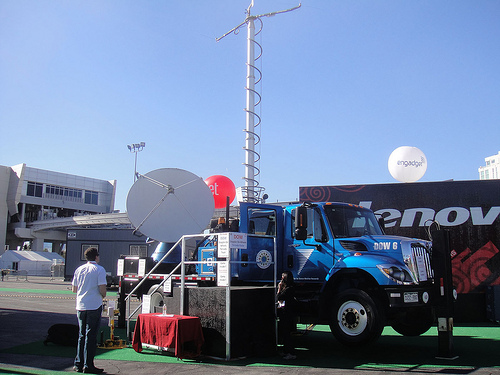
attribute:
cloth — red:
[130, 312, 206, 349]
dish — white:
[113, 157, 285, 302]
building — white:
[5, 139, 136, 268]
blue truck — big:
[244, 203, 437, 346]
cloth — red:
[132, 309, 209, 367]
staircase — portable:
[106, 208, 281, 363]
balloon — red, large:
[196, 167, 249, 219]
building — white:
[3, 158, 118, 211]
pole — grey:
[223, 3, 303, 199]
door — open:
[233, 198, 289, 289]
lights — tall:
[129, 135, 143, 176]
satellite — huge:
[103, 167, 218, 242]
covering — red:
[139, 316, 194, 345]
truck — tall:
[167, 194, 433, 352]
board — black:
[300, 168, 495, 328]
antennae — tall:
[207, 15, 312, 205]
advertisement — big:
[368, 201, 498, 228]